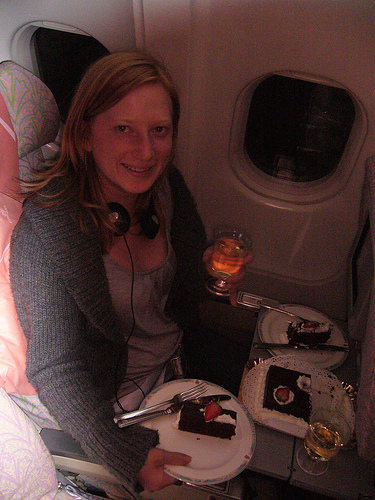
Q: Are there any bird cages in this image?
A: No, there are no bird cages.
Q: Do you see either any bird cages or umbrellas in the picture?
A: No, there are no bird cages or umbrellas.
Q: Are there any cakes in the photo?
A: Yes, there is a cake.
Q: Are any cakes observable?
A: Yes, there is a cake.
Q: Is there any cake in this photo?
A: Yes, there is a cake.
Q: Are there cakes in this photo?
A: Yes, there is a cake.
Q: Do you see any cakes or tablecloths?
A: Yes, there is a cake.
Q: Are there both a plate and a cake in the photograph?
A: Yes, there are both a cake and a plate.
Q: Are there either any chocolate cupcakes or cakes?
A: Yes, there is a chocolate cake.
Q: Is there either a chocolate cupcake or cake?
A: Yes, there is a chocolate cake.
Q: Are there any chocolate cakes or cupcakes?
A: Yes, there is a chocolate cake.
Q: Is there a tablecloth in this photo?
A: No, there are no tablecloths.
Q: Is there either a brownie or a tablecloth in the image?
A: No, there are no tablecloths or brownies.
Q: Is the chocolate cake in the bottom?
A: Yes, the cake is in the bottom of the image.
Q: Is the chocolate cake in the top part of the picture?
A: No, the cake is in the bottom of the image.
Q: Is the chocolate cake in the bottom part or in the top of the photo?
A: The cake is in the bottom of the image.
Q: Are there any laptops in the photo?
A: No, there are no laptops.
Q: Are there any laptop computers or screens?
A: No, there are no laptop computers or screens.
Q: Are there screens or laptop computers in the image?
A: No, there are no laptop computers or screens.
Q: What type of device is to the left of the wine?
A: The devices are earphones.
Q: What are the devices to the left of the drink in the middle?
A: The devices are earphones.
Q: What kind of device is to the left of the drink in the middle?
A: The devices are earphones.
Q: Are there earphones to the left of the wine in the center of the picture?
A: Yes, there are earphones to the left of the wine.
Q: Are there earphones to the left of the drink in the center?
A: Yes, there are earphones to the left of the wine.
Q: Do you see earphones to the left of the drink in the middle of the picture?
A: Yes, there are earphones to the left of the wine.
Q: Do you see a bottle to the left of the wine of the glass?
A: No, there are earphones to the left of the wine.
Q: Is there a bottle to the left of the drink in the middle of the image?
A: No, there are earphones to the left of the wine.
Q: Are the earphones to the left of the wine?
A: Yes, the earphones are to the left of the wine.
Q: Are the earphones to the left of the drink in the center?
A: Yes, the earphones are to the left of the wine.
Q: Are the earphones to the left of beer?
A: No, the earphones are to the left of the wine.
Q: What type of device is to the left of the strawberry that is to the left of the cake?
A: The devices are earphones.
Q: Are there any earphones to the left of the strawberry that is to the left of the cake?
A: Yes, there are earphones to the left of the strawberry.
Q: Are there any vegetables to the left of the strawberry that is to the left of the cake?
A: No, there are earphones to the left of the strawberry.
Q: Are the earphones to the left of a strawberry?
A: Yes, the earphones are to the left of a strawberry.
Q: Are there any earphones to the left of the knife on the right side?
A: Yes, there are earphones to the left of the knife.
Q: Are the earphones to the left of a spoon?
A: No, the earphones are to the left of the knife.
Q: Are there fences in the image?
A: No, there are no fences.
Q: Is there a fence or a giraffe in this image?
A: No, there are no fences or giraffes.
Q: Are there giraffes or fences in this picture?
A: No, there are no fences or giraffes.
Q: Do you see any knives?
A: Yes, there is a knife.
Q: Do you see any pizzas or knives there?
A: Yes, there is a knife.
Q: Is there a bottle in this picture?
A: No, there are no bottles.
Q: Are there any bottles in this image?
A: No, there are no bottles.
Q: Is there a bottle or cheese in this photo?
A: No, there are no bottles or cheese.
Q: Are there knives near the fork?
A: Yes, there is a knife near the fork.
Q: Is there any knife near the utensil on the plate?
A: Yes, there is a knife near the fork.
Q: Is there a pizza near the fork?
A: No, there is a knife near the fork.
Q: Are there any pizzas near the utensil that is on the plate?
A: No, there is a knife near the fork.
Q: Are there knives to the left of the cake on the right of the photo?
A: Yes, there is a knife to the left of the cake.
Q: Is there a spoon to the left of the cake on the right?
A: No, there is a knife to the left of the cake.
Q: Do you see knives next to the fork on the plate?
A: Yes, there is a knife next to the fork.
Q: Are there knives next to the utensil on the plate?
A: Yes, there is a knife next to the fork.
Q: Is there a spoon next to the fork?
A: No, there is a knife next to the fork.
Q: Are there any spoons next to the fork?
A: No, there is a knife next to the fork.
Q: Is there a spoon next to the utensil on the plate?
A: No, there is a knife next to the fork.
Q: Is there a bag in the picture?
A: No, there are no bags.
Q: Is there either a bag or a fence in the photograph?
A: No, there are no bags or fences.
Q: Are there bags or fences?
A: No, there are no bags or fences.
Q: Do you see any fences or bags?
A: No, there are no bags or fences.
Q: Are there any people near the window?
A: Yes, there is a person near the window.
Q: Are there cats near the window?
A: No, there is a person near the window.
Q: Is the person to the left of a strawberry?
A: Yes, the person is to the left of a strawberry.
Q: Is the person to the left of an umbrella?
A: No, the person is to the left of a strawberry.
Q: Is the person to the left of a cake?
A: Yes, the person is to the left of a cake.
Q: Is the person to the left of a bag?
A: No, the person is to the left of a cake.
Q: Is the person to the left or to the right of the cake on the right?
A: The person is to the left of the cake.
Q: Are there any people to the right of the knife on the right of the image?
A: No, the person is to the left of the knife.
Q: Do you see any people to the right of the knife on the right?
A: No, the person is to the left of the knife.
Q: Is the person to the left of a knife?
A: Yes, the person is to the left of a knife.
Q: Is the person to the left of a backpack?
A: No, the person is to the left of a knife.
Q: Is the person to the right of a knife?
A: No, the person is to the left of a knife.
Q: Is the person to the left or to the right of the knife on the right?
A: The person is to the left of the knife.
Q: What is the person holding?
A: The person is holding the glass.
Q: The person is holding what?
A: The person is holding the glass.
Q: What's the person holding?
A: The person is holding the glass.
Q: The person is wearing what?
A: The person is wearing a shirt.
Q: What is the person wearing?
A: The person is wearing a shirt.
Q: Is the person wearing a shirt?
A: Yes, the person is wearing a shirt.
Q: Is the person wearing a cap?
A: No, the person is wearing a shirt.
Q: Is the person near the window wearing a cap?
A: No, the person is wearing a shirt.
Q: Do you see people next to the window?
A: Yes, there is a person next to the window.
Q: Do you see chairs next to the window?
A: No, there is a person next to the window.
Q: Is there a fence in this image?
A: No, there are no fences.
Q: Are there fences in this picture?
A: No, there are no fences.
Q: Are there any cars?
A: No, there are no cars.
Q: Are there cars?
A: No, there are no cars.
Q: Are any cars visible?
A: No, there are no cars.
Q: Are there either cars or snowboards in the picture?
A: No, there are no cars or snowboards.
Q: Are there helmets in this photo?
A: No, there are no helmets.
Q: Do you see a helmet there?
A: No, there are no helmets.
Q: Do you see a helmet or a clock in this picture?
A: No, there are no helmets or clocks.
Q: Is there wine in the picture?
A: Yes, there is wine.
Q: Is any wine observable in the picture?
A: Yes, there is wine.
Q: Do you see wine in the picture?
A: Yes, there is wine.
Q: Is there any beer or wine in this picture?
A: Yes, there is wine.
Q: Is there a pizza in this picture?
A: No, there are no pizzas.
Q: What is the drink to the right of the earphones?
A: The drink is wine.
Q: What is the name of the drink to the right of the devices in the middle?
A: The drink is wine.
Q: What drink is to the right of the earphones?
A: The drink is wine.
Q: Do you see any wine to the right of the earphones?
A: Yes, there is wine to the right of the earphones.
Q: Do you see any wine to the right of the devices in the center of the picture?
A: Yes, there is wine to the right of the earphones.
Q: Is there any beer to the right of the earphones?
A: No, there is wine to the right of the earphones.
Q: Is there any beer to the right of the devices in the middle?
A: No, there is wine to the right of the earphones.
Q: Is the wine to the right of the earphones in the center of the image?
A: Yes, the wine is to the right of the earphones.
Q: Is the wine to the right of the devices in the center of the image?
A: Yes, the wine is to the right of the earphones.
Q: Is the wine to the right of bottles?
A: No, the wine is to the right of the earphones.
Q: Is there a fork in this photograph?
A: Yes, there is a fork.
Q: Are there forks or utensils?
A: Yes, there is a fork.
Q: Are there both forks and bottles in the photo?
A: No, there is a fork but no bottles.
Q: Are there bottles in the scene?
A: No, there are no bottles.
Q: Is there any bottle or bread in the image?
A: No, there are no bottles or breads.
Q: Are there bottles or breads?
A: No, there are no bottles or breads.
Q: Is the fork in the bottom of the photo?
A: Yes, the fork is in the bottom of the image.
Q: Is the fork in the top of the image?
A: No, the fork is in the bottom of the image.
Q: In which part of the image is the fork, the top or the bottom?
A: The fork is in the bottom of the image.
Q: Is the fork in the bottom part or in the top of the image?
A: The fork is in the bottom of the image.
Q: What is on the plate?
A: The fork is on the plate.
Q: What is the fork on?
A: The fork is on the plate.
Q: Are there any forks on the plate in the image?
A: Yes, there is a fork on the plate.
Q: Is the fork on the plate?
A: Yes, the fork is on the plate.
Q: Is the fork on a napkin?
A: No, the fork is on the plate.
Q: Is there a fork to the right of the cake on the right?
A: No, the fork is to the left of the cake.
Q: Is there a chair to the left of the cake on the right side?
A: No, there is a fork to the left of the cake.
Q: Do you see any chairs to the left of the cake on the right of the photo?
A: No, there is a fork to the left of the cake.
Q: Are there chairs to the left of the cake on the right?
A: No, there is a fork to the left of the cake.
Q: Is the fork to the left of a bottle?
A: No, the fork is to the left of the cake.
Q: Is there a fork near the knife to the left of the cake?
A: Yes, there is a fork near the knife.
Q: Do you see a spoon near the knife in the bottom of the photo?
A: No, there is a fork near the knife.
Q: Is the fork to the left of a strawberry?
A: Yes, the fork is to the left of a strawberry.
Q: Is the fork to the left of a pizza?
A: No, the fork is to the left of a strawberry.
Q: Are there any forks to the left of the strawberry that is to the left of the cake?
A: Yes, there is a fork to the left of the strawberry.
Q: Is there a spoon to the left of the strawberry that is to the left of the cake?
A: No, there is a fork to the left of the strawberry.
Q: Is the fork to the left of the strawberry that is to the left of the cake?
A: Yes, the fork is to the left of the strawberry.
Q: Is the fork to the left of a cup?
A: No, the fork is to the left of the strawberry.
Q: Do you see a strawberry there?
A: Yes, there is a strawberry.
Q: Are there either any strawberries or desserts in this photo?
A: Yes, there is a strawberry.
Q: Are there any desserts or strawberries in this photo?
A: Yes, there is a strawberry.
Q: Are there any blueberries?
A: No, there are no blueberries.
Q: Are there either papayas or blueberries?
A: No, there are no blueberries or papayas.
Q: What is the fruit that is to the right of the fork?
A: The fruit is a strawberry.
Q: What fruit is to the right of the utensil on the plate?
A: The fruit is a strawberry.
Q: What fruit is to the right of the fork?
A: The fruit is a strawberry.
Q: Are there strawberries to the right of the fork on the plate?
A: Yes, there is a strawberry to the right of the fork.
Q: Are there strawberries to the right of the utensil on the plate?
A: Yes, there is a strawberry to the right of the fork.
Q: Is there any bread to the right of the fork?
A: No, there is a strawberry to the right of the fork.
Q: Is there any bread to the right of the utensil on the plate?
A: No, there is a strawberry to the right of the fork.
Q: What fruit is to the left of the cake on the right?
A: The fruit is a strawberry.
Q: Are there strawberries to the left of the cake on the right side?
A: Yes, there is a strawberry to the left of the cake.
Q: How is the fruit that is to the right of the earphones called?
A: The fruit is a strawberry.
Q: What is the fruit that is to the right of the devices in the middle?
A: The fruit is a strawberry.